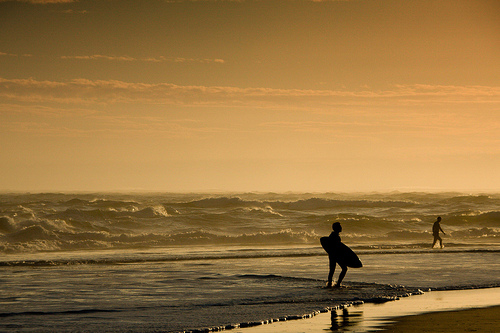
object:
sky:
[1, 4, 500, 197]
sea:
[2, 190, 500, 260]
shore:
[0, 256, 500, 332]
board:
[320, 234, 367, 270]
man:
[326, 220, 350, 287]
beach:
[3, 245, 495, 332]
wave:
[3, 189, 500, 247]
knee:
[340, 265, 352, 276]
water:
[3, 188, 500, 253]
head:
[330, 222, 346, 232]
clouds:
[1, 0, 500, 193]